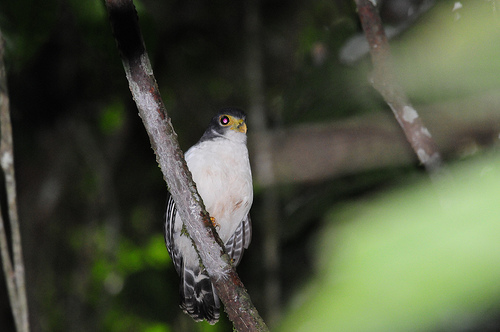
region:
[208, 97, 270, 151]
head of a bird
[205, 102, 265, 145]
a head of a bird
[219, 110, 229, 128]
eye of a bird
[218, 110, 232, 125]
an eye of a bird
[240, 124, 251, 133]
peck of a bird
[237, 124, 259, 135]
a peck of a bird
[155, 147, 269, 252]
body of a bird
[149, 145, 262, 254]
a body of a bird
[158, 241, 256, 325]
tail of a bird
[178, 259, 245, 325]
a tail of a bird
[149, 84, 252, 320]
bird perched on a branch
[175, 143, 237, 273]
bird's feathers are white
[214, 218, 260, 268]
feather of a bird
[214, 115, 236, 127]
an eye of a bird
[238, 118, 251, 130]
peck of a bird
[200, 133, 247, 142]
neck of a bird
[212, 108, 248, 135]
a head of a bird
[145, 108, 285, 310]
bird on a branch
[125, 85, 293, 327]
a small bird on a branch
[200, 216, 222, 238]
the bird's claws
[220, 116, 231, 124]
the eye of the bird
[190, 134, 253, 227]
the white breast of the bird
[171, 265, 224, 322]
the bird's tail feathers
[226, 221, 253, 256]
white and black striped feathers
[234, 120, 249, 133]
the bird's orange beak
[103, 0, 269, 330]
a branch with a bird on it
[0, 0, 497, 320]
trees and branches behind the bird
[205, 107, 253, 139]
the bird's small head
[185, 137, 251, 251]
white chest on the bird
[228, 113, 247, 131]
yellow beak of the bird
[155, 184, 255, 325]
gray feathers of the bird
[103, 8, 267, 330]
branch the bird is perched on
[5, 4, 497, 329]
branches and leaves in the background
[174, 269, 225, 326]
tail feathers of the bird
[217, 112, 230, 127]
eye of the bird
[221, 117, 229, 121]
red glare in the bird's eye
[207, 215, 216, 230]
foot of the bird